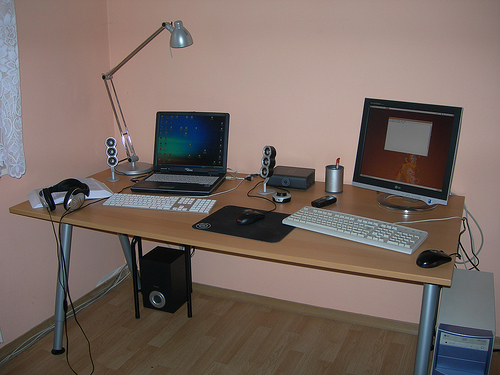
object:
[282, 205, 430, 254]
keyboard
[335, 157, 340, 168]
blue shirt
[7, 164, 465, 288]
tan desk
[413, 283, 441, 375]
table`s legs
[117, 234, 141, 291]
table`s legs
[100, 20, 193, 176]
lamp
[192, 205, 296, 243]
mouse pad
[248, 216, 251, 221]
black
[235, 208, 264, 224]
mouse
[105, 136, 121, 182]
speaker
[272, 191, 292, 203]
mouse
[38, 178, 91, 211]
head phones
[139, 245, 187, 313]
speaker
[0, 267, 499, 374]
floor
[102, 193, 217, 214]
computer equpment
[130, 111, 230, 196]
computer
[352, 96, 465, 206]
computer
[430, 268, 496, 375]
cpu computer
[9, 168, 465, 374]
desk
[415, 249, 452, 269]
computer mouse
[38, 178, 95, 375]
earphones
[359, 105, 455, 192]
screen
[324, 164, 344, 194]
can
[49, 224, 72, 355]
legs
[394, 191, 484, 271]
wires